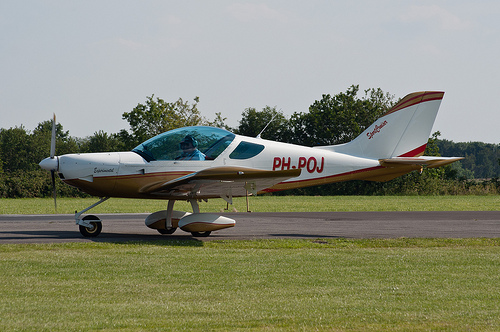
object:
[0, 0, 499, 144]
sky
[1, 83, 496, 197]
trees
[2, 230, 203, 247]
shadows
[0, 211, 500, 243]
ground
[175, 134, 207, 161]
pilot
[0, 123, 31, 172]
bushes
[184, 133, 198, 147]
headphones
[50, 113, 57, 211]
propeller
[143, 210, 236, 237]
gear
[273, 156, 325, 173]
letters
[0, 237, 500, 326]
field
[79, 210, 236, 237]
gear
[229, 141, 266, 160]
window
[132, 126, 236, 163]
cockpit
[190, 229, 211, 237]
wheel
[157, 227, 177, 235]
wheel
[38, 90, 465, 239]
plane